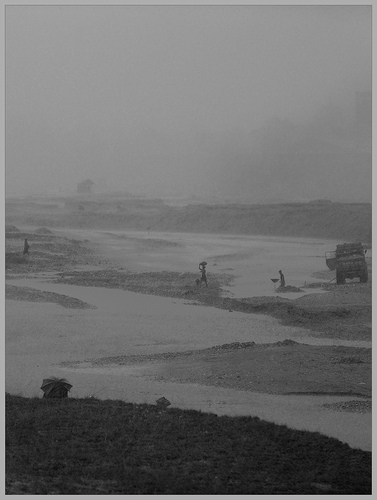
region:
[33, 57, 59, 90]
white clouds in blue sky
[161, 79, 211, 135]
white clouds in blue sky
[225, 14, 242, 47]
white clouds in blue sky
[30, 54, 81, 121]
white clouds in blue sky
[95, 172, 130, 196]
white clouds in blue sky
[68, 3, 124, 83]
white clouds in blue sky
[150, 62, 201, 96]
white clouds in blue sky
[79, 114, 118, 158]
white clouds in blue sky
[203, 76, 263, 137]
white clouds in blue sky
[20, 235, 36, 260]
THAT IS A PERSON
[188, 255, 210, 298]
THAT IS A PERSON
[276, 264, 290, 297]
THAT IS A PERSON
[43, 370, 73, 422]
THAT IS A PERSON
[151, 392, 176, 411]
THAT IS A PERSON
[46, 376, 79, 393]
THAT IS AN UMBRELLA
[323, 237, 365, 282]
THAT IS A JEEP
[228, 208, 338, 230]
THAT IS A HILL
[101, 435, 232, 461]
THIS IS A HILL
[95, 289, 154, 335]
THAT IS A FLAT LAND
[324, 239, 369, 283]
vehicle sits on the bank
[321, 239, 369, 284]
vehcicle is near the water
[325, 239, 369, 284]
vehicle has four wheels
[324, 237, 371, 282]
vehicle has a doo open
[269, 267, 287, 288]
human is near vehicle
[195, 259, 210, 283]
human is walking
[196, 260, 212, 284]
human is walking as they carry something on their head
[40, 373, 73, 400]
person holds umbrella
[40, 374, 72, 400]
person sits with umbrella over themselves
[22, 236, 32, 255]
person walks across the sand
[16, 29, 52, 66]
white clouds in blue sky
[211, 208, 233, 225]
white clouds in blue sky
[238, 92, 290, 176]
white clouds in blue sky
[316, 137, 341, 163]
white clouds in blue sky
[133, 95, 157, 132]
white clouds in blue sky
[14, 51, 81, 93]
white clouds in blue sky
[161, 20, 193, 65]
white clouds in blue sky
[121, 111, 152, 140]
white clouds in blue sky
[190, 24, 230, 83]
white clouds in blue sky